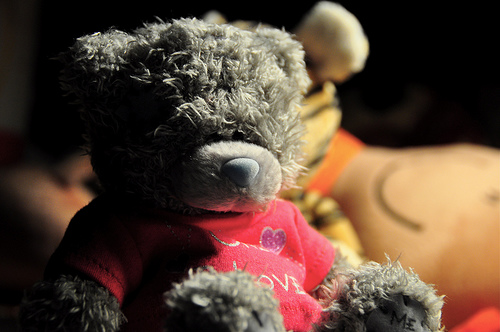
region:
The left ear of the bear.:
[80, 34, 131, 85]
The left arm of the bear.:
[40, 211, 122, 298]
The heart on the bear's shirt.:
[264, 225, 286, 249]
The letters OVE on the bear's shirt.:
[245, 266, 307, 291]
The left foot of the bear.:
[170, 281, 279, 330]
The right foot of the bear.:
[325, 269, 443, 329]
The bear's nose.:
[222, 160, 260, 184]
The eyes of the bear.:
[201, 129, 258, 142]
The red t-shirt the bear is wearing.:
[47, 173, 343, 330]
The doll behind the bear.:
[241, 13, 498, 281]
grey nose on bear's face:
[213, 154, 262, 192]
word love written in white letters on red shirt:
[232, 249, 302, 298]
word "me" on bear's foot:
[376, 297, 418, 329]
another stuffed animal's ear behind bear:
[296, 18, 362, 93]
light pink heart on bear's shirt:
[256, 224, 296, 260]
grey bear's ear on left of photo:
[75, 30, 133, 88]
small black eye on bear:
[173, 120, 227, 147]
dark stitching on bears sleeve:
[80, 248, 124, 283]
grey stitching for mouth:
[223, 187, 259, 217]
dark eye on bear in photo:
[232, 121, 260, 150]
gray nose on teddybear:
[222, 156, 259, 187]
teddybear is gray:
[52, 17, 444, 329]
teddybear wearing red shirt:
[51, 20, 443, 330]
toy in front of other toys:
[51, 20, 441, 330]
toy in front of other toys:
[190, 4, 369, 272]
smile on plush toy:
[375, 155, 425, 239]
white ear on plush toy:
[297, 3, 365, 86]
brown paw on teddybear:
[313, 255, 444, 330]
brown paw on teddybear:
[167, 265, 282, 329]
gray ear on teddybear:
[74, 26, 140, 83]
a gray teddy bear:
[33, 8, 445, 329]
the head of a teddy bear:
[67, 25, 319, 220]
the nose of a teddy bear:
[216, 154, 263, 189]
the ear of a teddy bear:
[255, 28, 316, 100]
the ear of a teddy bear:
[62, 20, 127, 92]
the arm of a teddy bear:
[319, 246, 445, 330]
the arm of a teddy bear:
[31, 208, 138, 330]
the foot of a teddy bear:
[163, 281, 288, 330]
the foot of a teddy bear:
[333, 271, 443, 329]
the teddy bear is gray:
[71, 18, 330, 252]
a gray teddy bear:
[61, 12, 333, 252]